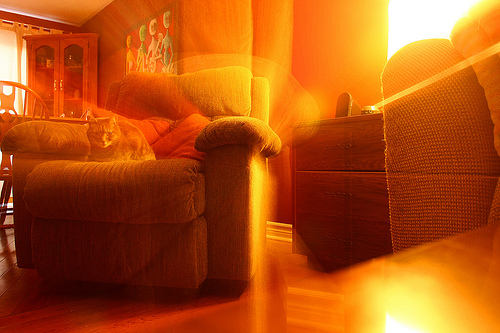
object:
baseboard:
[266, 220, 293, 243]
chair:
[0, 80, 51, 231]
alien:
[135, 24, 148, 72]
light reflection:
[341, 256, 500, 333]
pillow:
[91, 106, 169, 146]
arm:
[380, 33, 500, 259]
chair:
[383, 0, 500, 258]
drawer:
[293, 118, 389, 171]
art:
[122, 0, 181, 76]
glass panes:
[35, 44, 56, 68]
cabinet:
[20, 33, 99, 120]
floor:
[0, 212, 500, 333]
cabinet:
[288, 112, 396, 274]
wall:
[79, 0, 387, 245]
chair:
[0, 64, 283, 305]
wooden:
[313, 128, 379, 243]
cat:
[85, 113, 157, 163]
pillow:
[150, 111, 214, 163]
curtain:
[0, 18, 68, 116]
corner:
[61, 15, 103, 34]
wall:
[0, 10, 80, 118]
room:
[0, 0, 500, 330]